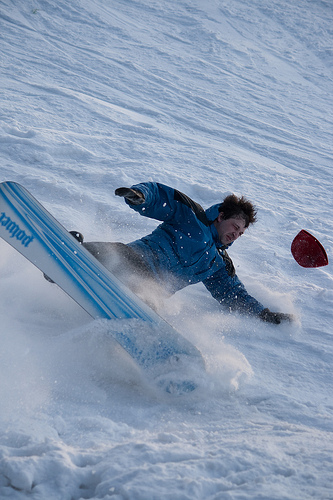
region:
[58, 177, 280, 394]
man falling in snow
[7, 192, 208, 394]
under side of snowboard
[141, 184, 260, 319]
blue jacket with black shoulders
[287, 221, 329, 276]
knit hat in the air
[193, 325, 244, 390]
snow kicked up by snowboard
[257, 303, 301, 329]
black glove on ground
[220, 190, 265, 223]
hair on head flying up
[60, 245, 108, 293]
blue design on white board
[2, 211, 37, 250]
blue word on snowboard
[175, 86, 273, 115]
packed snow with lines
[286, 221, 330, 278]
a red stocking cap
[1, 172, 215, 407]
snowboard with blue and white design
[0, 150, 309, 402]
man about to eat some snow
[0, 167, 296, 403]
man proving he doesn't know how to ride a snowboard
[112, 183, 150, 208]
hand inside a mitten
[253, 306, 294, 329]
hand inside a mitten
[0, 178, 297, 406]
person wearing blue and white coat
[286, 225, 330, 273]
red hat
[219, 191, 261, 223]
some brown hair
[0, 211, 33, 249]
blue writing on snowboard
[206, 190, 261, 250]
the head of a man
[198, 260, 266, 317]
the arm of a man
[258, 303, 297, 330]
a black glove on the man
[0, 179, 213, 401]
a blue and white snowboard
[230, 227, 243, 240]
the nose of a man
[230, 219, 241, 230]
the eye of a man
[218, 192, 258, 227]
the hair of a man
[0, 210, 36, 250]
blue writing on the snowboard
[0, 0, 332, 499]
white snow on the ground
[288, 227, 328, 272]
red cap flying through the air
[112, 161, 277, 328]
a blue winter jacket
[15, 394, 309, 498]
packed fresh white snow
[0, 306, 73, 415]
snow being flung into the air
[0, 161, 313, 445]
a man falling off of his snowboard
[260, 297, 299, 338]
a black snow boarding glove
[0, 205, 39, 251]
a logo on the snowboard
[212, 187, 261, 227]
the man's brown hair waving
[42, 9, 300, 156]
fresh snow with tracks in it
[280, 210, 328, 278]
a red knit cap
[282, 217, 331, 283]
a red hat flying in the air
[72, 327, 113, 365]
snow flying up into the air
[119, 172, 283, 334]
a wearing a blue parka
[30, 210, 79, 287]
blue lines on white snowboard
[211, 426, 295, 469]
icy white snow on the ground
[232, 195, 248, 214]
dark brown hair on a head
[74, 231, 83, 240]
the tip of a black shoe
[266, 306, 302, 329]
a gloved hand in the snow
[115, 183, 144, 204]
a black glove on a hand